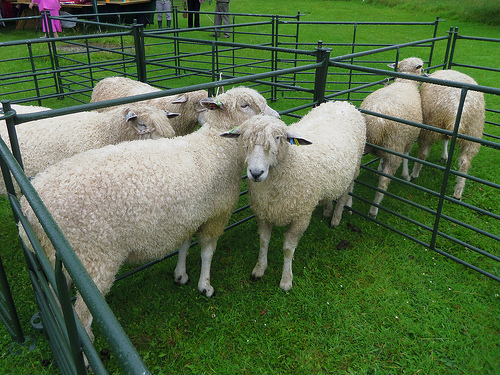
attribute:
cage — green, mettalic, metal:
[3, 10, 498, 371]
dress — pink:
[36, 3, 65, 29]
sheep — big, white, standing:
[228, 99, 366, 288]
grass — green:
[5, 1, 500, 373]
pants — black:
[184, 2, 204, 25]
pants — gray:
[213, 2, 233, 41]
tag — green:
[294, 139, 298, 145]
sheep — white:
[21, 85, 283, 318]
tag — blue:
[288, 141, 295, 146]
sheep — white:
[95, 74, 208, 128]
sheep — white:
[4, 102, 183, 182]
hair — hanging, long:
[245, 118, 287, 158]